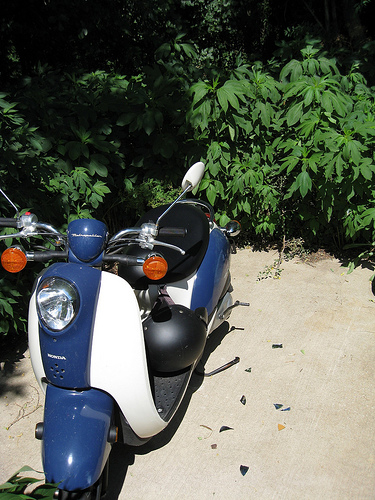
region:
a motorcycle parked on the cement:
[11, 163, 311, 497]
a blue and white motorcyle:
[16, 170, 270, 459]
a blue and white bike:
[1, 181, 249, 463]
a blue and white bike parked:
[7, 176, 245, 468]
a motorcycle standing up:
[5, 167, 291, 497]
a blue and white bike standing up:
[4, 181, 261, 496]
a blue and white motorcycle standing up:
[8, 184, 271, 489]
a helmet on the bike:
[131, 266, 216, 398]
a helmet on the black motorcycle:
[135, 277, 222, 381]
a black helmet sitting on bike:
[121, 276, 219, 379]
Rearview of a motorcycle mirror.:
[183, 160, 204, 193]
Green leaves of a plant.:
[0, 466, 65, 499]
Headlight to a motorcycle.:
[32, 276, 81, 331]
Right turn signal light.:
[143, 256, 168, 282]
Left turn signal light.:
[1, 250, 26, 273]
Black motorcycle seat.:
[115, 200, 209, 290]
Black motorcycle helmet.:
[143, 304, 211, 374]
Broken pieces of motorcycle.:
[216, 341, 291, 486]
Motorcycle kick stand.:
[216, 299, 250, 323]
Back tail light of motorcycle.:
[227, 218, 240, 238]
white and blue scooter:
[0, 155, 274, 482]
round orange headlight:
[140, 252, 170, 286]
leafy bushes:
[2, 30, 357, 265]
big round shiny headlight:
[25, 276, 86, 340]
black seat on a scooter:
[112, 192, 217, 293]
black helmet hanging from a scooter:
[133, 292, 212, 373]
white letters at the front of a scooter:
[43, 350, 69, 366]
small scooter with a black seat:
[8, 196, 235, 497]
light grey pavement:
[215, 338, 357, 462]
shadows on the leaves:
[6, 20, 218, 208]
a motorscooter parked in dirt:
[0, 150, 252, 499]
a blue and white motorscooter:
[4, 154, 240, 499]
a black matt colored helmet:
[135, 295, 212, 382]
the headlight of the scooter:
[33, 274, 78, 333]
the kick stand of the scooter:
[193, 350, 248, 376]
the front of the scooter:
[20, 267, 143, 497]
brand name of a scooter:
[39, 346, 75, 366]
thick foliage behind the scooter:
[190, 78, 373, 263]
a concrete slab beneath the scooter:
[237, 323, 352, 486]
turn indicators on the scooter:
[0, 243, 169, 279]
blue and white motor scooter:
[1, 160, 231, 496]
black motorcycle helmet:
[145, 302, 204, 376]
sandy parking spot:
[1, 246, 370, 496]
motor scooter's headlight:
[35, 280, 76, 330]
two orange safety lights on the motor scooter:
[4, 248, 166, 278]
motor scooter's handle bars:
[0, 215, 186, 253]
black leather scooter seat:
[117, 205, 203, 283]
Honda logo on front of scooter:
[45, 352, 65, 360]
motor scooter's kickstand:
[196, 357, 238, 375]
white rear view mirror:
[180, 162, 204, 190]